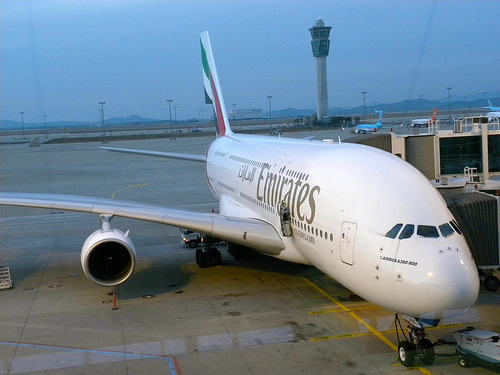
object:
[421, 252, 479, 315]
nose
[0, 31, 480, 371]
airplane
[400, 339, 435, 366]
wheels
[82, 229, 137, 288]
engine`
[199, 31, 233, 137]
tail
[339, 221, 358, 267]
door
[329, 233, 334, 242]
window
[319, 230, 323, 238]
window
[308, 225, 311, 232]
window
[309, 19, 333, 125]
tower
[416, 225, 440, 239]
window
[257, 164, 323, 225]
name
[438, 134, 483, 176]
cart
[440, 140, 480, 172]
luggage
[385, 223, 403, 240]
windows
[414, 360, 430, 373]
line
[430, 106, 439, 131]
stick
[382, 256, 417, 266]
numbers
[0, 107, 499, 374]
airport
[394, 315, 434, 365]
gear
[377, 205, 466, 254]
cockpit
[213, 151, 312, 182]
row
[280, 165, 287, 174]
windows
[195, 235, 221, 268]
gear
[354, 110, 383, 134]
airplane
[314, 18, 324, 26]
top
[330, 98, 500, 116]
hill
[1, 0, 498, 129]
distance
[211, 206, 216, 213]
cone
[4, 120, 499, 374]
foreground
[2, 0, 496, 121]
sky